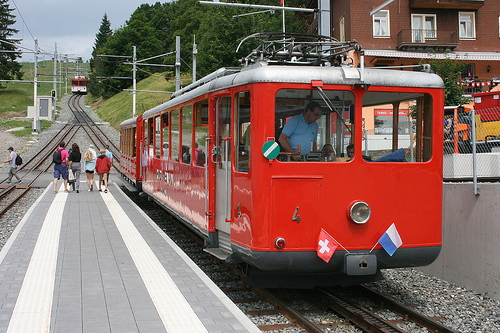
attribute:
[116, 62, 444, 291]
train — red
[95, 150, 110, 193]
person — walking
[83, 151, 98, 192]
person — walking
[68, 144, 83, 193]
person — walking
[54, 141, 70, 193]
person — walking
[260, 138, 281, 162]
sign — green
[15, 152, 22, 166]
backpack — black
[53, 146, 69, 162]
shirt — pink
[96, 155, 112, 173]
jacket — red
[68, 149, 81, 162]
shirt — black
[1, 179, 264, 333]
pavement — grey, white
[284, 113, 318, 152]
shirt — blue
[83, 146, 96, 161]
hair — blonde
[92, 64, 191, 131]
grass — green